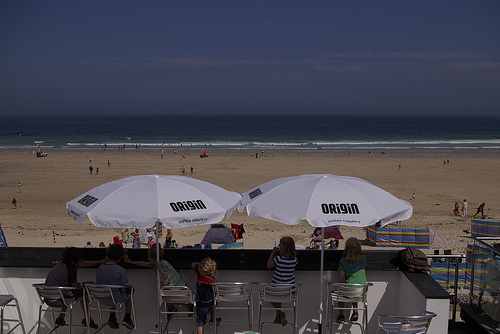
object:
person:
[124, 244, 196, 318]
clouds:
[0, 50, 500, 74]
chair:
[258, 282, 301, 333]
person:
[191, 257, 224, 334]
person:
[96, 244, 135, 330]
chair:
[327, 283, 372, 333]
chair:
[378, 311, 437, 334]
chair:
[160, 286, 196, 333]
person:
[11, 198, 17, 210]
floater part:
[412, 147, 427, 175]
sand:
[216, 160, 280, 177]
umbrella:
[237, 173, 414, 334]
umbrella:
[66, 175, 242, 334]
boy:
[96, 243, 136, 330]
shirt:
[95, 263, 128, 306]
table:
[0, 246, 452, 333]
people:
[312, 230, 326, 241]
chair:
[209, 282, 255, 334]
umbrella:
[263, 169, 382, 221]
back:
[209, 280, 255, 333]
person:
[462, 199, 468, 216]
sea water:
[0, 115, 499, 152]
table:
[217, 241, 243, 249]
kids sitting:
[43, 237, 367, 334]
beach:
[1, 142, 498, 253]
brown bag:
[401, 247, 428, 273]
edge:
[305, 178, 322, 219]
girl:
[336, 237, 367, 323]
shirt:
[337, 254, 369, 293]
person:
[266, 234, 299, 326]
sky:
[4, 0, 498, 120]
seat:
[216, 288, 251, 305]